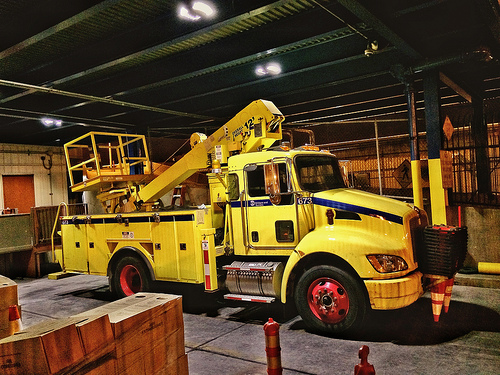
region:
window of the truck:
[297, 148, 352, 198]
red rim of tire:
[309, 277, 351, 314]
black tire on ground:
[278, 266, 324, 323]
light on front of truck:
[353, 242, 415, 309]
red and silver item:
[244, 307, 307, 374]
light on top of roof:
[24, 111, 68, 151]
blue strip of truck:
[233, 192, 350, 223]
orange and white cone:
[419, 271, 469, 333]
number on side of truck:
[290, 188, 317, 218]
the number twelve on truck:
[233, 97, 273, 142]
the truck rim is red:
[118, 268, 149, 311]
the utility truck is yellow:
[108, 103, 496, 308]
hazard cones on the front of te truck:
[416, 275, 459, 352]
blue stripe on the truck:
[219, 195, 396, 223]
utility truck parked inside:
[32, 95, 484, 369]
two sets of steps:
[208, 254, 283, 337]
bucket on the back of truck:
[68, 122, 199, 206]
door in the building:
[2, 171, 44, 282]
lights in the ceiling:
[167, 5, 314, 85]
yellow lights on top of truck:
[270, 143, 332, 150]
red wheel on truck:
[284, 178, 496, 348]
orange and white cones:
[386, 178, 486, 335]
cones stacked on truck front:
[350, 186, 495, 351]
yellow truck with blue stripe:
[86, 133, 438, 342]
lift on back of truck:
[44, 94, 324, 234]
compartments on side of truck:
[42, 205, 237, 310]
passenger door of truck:
[186, 131, 327, 293]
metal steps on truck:
[212, 191, 318, 339]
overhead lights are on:
[163, 1, 345, 111]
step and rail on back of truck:
[27, 179, 122, 286]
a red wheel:
[311, 285, 346, 321]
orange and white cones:
[427, 257, 448, 322]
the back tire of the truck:
[113, 262, 148, 289]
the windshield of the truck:
[297, 161, 335, 186]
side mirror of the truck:
[268, 187, 287, 206]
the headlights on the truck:
[365, 253, 405, 275]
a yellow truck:
[83, 139, 384, 292]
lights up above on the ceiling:
[170, 2, 223, 27]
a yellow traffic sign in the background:
[386, 160, 421, 188]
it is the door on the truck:
[234, 165, 297, 254]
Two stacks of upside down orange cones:
[426, 225, 457, 322]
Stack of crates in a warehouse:
[89, 291, 197, 371]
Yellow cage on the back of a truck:
[60, 130, 151, 182]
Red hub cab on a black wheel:
[303, 274, 353, 324]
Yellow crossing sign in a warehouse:
[387, 155, 414, 185]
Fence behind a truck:
[147, 125, 499, 199]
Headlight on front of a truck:
[366, 248, 404, 273]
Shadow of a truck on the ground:
[375, 312, 493, 348]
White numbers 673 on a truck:
[296, 193, 313, 208]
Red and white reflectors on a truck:
[204, 237, 213, 290]